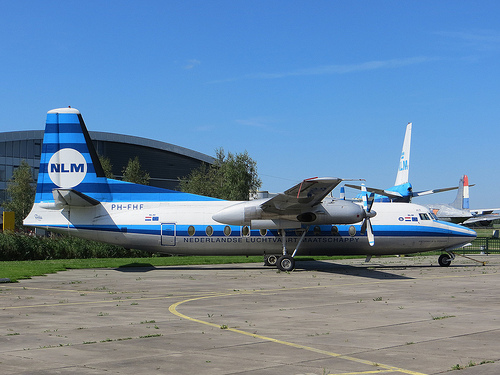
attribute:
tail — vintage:
[15, 91, 109, 208]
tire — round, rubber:
[275, 254, 297, 271]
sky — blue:
[195, 15, 472, 165]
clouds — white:
[167, 48, 461, 120]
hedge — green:
[168, 161, 272, 201]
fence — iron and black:
[421, 224, 498, 261]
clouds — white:
[207, 41, 463, 158]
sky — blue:
[1, 1, 499, 213]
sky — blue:
[5, 7, 480, 132]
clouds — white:
[181, 49, 480, 80]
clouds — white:
[184, 29, 498, 213]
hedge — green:
[197, 155, 257, 188]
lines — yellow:
[240, 330, 335, 360]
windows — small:
[418, 209, 433, 220]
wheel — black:
[437, 255, 450, 267]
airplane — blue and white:
[23, 102, 476, 282]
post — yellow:
[10, 197, 114, 292]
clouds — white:
[53, 49, 308, 131]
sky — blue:
[17, 6, 497, 74]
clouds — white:
[239, 44, 439, 84]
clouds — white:
[211, 49, 479, 90]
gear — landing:
[266, 221, 317, 255]